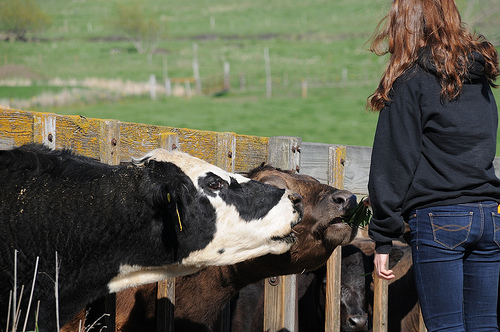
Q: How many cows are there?
A: 3.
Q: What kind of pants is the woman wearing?
A: Jeans.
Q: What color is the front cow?
A: Black and white.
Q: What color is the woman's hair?
A: Brown.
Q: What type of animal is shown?
A: Cows.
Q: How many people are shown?
A: 1.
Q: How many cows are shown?
A: 3.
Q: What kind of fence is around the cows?
A: WOODEN.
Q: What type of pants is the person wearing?
A: Jeans.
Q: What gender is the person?
A: Female.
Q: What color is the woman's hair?
A: Red.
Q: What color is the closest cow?
A: Black and white.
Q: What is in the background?
A: Grassy field.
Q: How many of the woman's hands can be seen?
A: 1.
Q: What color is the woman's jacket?
A: Black.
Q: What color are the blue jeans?
A: Blue.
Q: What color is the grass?
A: Green.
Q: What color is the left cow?
A: Black.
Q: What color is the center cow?
A: Brown.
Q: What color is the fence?
A: Brown.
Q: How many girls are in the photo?
A: One.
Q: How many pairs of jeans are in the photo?
A: One.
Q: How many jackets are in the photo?
A: One.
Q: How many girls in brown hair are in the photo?
A: One.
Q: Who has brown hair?
A: A woman.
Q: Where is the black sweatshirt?
A: On the woman.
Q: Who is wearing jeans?
A: A woman.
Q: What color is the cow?
A: Black and white.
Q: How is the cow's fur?
A: Fluffy.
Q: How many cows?
A: Two.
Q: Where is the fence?
A: Around the pen.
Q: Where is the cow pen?
A: By a grassy hill.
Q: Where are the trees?
A: Next to pen.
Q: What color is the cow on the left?
A: Black.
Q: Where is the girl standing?
A: In front of the cattle pen.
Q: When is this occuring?
A: During the day.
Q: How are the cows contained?
A: In a pen.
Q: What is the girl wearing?
A: Jeans and a hoodie.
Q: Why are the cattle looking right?
A: The girl is there.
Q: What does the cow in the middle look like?
A: Black and white.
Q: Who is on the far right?
A: The girl.